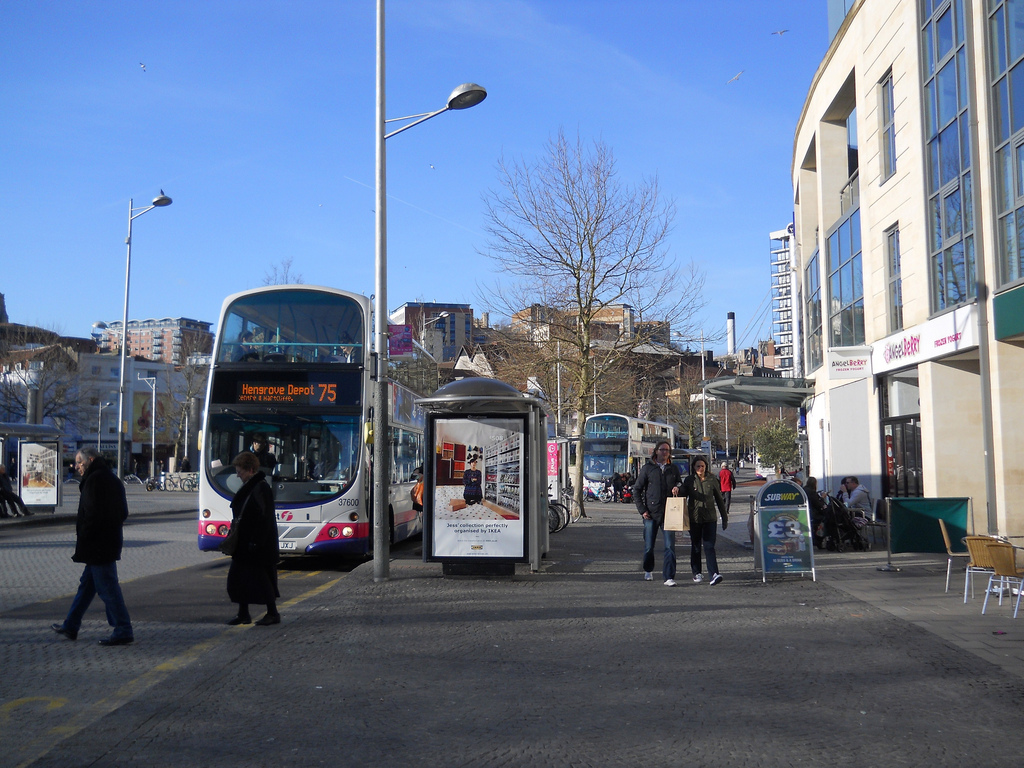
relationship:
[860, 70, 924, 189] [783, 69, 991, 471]
window on building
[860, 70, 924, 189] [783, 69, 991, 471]
window in building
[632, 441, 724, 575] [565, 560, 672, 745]
people on street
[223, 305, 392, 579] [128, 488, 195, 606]
bus on road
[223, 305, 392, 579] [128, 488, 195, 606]
bus in road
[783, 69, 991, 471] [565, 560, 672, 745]
building in street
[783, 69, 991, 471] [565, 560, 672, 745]
building on street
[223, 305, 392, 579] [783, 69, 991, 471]
bus near building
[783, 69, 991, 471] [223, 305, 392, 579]
building near bus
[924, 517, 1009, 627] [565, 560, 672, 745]
chair on street